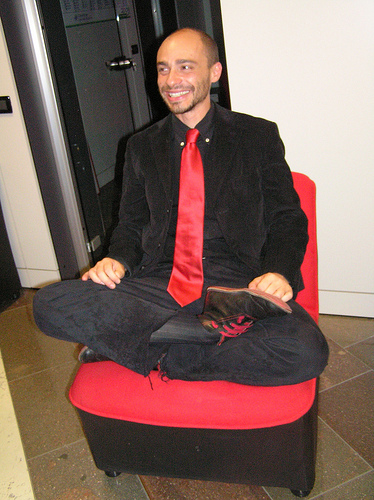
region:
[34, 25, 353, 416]
a man sitting on a chair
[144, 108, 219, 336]
the tie is red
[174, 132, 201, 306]
The tie the man is wearing.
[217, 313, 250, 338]
The red shoe laces on the man's shoe.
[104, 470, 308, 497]
The feet of the chair the man is sitting in.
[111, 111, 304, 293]
The black jacket the man is wearing.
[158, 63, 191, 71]
The eyes of the man.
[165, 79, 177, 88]
The nose of the man.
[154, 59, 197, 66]
The eyebrows the man is wearing.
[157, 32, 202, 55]
The bald head of the man.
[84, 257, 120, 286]
The left hand of the man.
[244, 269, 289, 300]
The right hand of the man.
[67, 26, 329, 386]
the man sitting on the chair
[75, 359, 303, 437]
the chair is red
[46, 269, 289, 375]
the legs are crossed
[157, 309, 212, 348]
the man wearing black socks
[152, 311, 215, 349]
the socks are pin striped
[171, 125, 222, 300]
the man wearing the tie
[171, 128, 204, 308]
the tie is red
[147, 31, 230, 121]
the man is smiling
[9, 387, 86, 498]
the floor is tiled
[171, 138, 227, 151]
the buttons on the collar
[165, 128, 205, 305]
the long red tie on the man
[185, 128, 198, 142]
the knot on the man's red tie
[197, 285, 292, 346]
the shoe on the man's foot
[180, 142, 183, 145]
the button on the man's collar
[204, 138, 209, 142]
the button on the man's collar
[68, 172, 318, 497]
the chair the man is sitting on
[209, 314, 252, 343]
the laces on the man's shoe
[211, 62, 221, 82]
the ear on the man's head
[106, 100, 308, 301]
the black jacket the man is wearing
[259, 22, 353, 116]
white wall for room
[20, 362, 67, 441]
tile floor easy for maintenance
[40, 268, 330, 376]
legs criss crossed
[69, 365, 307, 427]
red cushion for comfort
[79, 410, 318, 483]
black base for support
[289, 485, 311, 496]
chair's front foot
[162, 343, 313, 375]
black pants for legs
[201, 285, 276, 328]
black ankle shoes with red laces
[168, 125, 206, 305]
red tie for style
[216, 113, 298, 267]
black jacket for style